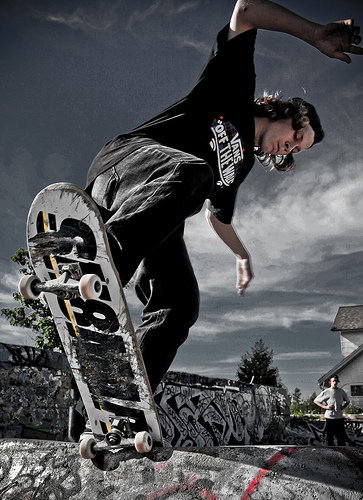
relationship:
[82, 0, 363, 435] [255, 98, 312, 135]
guy with hair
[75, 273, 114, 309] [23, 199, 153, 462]
wheel on skateboard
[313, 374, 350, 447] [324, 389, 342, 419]
guy in shirt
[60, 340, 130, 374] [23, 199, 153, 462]
letter on skateboard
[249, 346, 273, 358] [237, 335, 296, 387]
needles on tree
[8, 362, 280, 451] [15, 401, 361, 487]
side of ramp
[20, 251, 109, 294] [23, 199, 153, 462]
wheels of skateboard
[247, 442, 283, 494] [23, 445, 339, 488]
line on ground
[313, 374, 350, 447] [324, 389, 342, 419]
guy with shirt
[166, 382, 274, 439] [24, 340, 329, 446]
graffiti on wall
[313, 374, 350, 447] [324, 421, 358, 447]
guy with jeans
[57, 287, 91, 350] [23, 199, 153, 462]
line on skateboard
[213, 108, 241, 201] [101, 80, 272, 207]
letters on shirt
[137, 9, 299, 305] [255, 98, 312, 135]
guy with hair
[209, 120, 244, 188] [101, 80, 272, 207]
letters on shirt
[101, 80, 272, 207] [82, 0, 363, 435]
shirt of guy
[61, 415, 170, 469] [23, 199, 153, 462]
wheels of skateboard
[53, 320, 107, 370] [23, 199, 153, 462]
scuffs on skateboard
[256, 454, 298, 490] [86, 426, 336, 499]
paint on concrete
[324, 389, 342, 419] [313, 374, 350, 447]
shirt on guy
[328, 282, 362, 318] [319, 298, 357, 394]
roof of home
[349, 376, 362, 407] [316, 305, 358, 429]
window of home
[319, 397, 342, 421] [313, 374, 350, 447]
hands of guy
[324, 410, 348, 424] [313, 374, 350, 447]
hips of guy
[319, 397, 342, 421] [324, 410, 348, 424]
hands on hips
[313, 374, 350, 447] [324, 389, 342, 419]
guy wearing shirt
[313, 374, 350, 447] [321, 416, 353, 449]
guy wearing pants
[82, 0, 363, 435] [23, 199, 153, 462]
guy riding skateboard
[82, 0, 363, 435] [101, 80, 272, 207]
guy wearing shirt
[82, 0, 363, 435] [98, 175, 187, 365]
guy wearing jeans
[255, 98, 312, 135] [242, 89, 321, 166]
hair on head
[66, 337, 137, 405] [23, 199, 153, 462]
scraping on skateboard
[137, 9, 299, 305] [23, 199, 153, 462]
guy on skateboard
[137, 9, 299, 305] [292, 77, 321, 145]
guy wearing hat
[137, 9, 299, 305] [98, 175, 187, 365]
guy wearing jeans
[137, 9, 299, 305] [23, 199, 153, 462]
guy leaning on skateboard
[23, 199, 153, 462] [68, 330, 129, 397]
skateboard with scratches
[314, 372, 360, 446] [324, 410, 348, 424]
guy with hips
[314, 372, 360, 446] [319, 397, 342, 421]
guy with hands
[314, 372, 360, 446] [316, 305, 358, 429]
guy near home